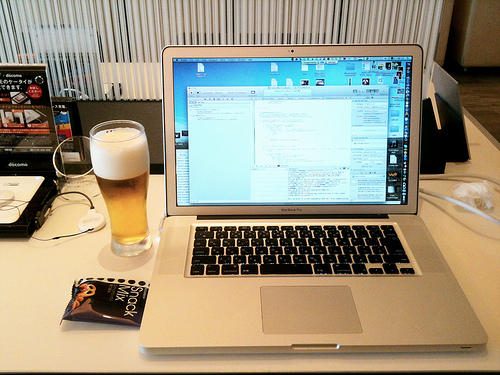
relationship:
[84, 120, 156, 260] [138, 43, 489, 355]
beer next to laptop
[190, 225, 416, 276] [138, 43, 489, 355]
keyboard of laptop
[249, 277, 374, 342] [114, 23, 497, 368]
trackpad of computer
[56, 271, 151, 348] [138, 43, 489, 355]
snack next to laptop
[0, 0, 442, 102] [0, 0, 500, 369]
shutters in computer's room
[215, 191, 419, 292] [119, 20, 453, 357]
keyboard on laptop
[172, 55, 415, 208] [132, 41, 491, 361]
laptop screen on laptop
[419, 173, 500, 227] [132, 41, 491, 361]
cable beside laptop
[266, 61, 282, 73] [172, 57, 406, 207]
icon on screen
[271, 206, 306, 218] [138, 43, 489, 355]
letters on laptop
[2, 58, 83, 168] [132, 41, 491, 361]
magazines near laptop